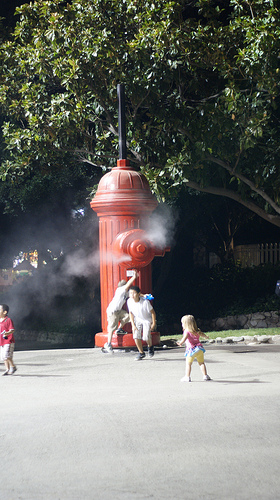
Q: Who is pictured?
A: Children playing.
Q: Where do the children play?
A: Under an oversized fire hydrant.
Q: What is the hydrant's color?
A: Red.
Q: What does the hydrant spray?
A: Water.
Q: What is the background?
A: Large lush trees.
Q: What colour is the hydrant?
A: Red.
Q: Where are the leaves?
A: On the tree.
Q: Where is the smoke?
A: On the hydrant.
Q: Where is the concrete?
A: In the ground.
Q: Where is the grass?
A: On the ground.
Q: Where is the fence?
A: Behind the trees.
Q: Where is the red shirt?
A: On the boy.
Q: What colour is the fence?
A: White.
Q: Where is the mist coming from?
A: A giant hydrant.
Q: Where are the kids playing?
A: Near the hydrant.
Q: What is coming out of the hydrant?
A: A mist.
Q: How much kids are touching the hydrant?
A: One.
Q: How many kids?
A: 4.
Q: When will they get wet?
A: Soon.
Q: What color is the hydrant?
A: Red.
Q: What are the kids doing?
A: Playing.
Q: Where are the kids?
A: Playground.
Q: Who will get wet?
A: The kids.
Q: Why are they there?
A: To play.